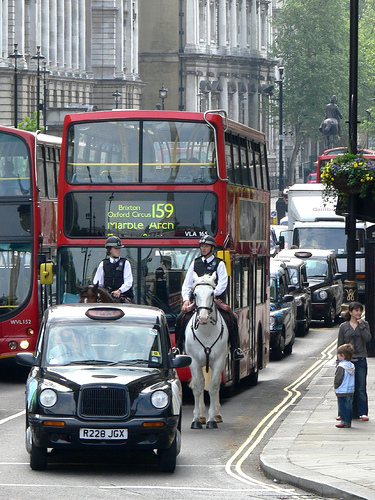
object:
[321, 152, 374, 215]
plant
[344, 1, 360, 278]
pole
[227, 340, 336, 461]
lines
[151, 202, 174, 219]
number 159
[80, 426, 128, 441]
plate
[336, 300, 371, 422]
people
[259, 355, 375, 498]
sidewalk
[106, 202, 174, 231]
sign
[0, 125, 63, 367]
buses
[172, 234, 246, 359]
man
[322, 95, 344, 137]
horseback rider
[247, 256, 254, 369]
doors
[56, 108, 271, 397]
bus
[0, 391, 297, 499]
street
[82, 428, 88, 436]
letters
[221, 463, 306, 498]
line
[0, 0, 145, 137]
buildings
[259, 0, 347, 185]
trees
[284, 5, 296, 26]
leaves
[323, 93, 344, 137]
man statue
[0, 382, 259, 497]
road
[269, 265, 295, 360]
car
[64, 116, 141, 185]
window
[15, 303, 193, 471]
car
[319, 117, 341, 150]
horse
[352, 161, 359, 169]
flower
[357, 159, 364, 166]
flower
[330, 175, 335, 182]
flower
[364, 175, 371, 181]
flower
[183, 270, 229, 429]
horse